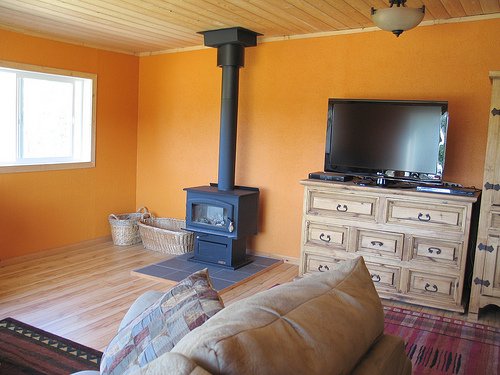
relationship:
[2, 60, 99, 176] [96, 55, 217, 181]
window in orange wall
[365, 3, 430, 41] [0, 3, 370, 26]
light on ceiling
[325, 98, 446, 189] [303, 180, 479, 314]
flat screen tv on dresser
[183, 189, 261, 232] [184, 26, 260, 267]
wood burning stove that is black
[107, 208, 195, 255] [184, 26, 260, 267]
firewood in baskets near stove for firewood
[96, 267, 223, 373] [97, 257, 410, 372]
multi colored pillow on couch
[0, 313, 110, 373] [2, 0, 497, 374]
rug in living room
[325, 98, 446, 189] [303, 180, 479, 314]
tv on a wooden dresser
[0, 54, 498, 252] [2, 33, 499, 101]
walls painted orange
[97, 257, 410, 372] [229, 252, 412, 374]
pillow couch cushion that tan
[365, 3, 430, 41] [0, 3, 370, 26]
light fixture on ceiling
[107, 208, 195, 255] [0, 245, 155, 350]
two baskets on floor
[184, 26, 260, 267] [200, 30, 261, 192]
fireplace that black with large pipe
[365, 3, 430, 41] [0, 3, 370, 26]
light hanging from ceiling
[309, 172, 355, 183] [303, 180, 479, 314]
box that is black on dresser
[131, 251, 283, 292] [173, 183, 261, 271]
stone tiles are under stove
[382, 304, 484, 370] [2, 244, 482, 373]
rug on floor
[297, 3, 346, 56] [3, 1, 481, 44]
panel on ceiling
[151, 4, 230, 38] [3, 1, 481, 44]
panel on ceiling